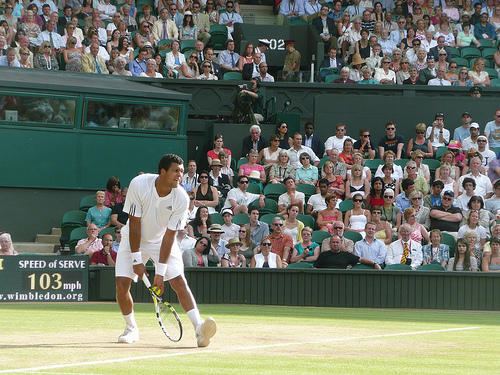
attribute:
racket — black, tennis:
[105, 275, 202, 365]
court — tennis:
[253, 292, 402, 375]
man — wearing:
[83, 122, 229, 344]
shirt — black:
[321, 247, 355, 271]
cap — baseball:
[208, 222, 225, 240]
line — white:
[248, 323, 290, 355]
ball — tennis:
[142, 268, 168, 305]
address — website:
[3, 286, 79, 309]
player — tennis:
[84, 128, 213, 312]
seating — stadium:
[224, 76, 444, 270]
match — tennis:
[30, 118, 457, 374]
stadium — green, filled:
[59, 102, 176, 193]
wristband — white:
[121, 249, 153, 274]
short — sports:
[139, 242, 195, 279]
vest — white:
[351, 209, 370, 233]